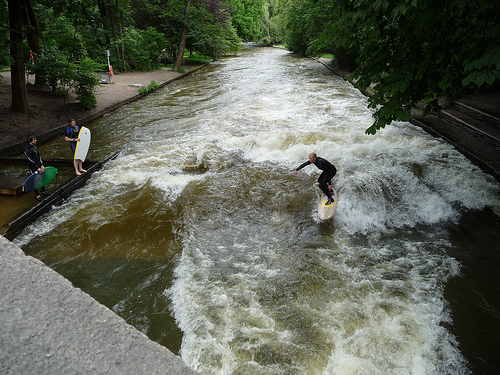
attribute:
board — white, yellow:
[73, 126, 91, 162]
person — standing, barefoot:
[64, 117, 88, 175]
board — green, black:
[22, 165, 60, 192]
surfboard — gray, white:
[316, 185, 338, 223]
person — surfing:
[293, 152, 337, 205]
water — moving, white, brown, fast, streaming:
[0, 42, 499, 375]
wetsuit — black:
[295, 156, 336, 206]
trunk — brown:
[8, 1, 39, 121]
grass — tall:
[140, 81, 163, 96]